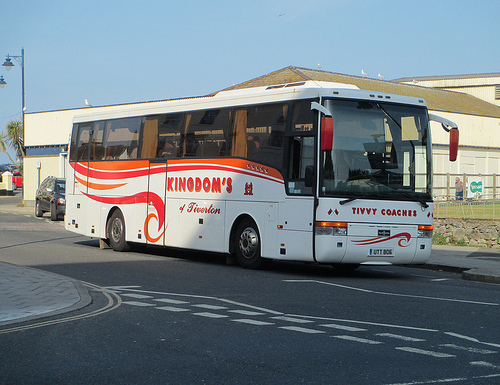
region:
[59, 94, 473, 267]
white, red and orange bus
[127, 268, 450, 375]
gray street with white lines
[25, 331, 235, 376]
gray street without lines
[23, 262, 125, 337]
gray sidewalk with lines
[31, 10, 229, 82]
white clouds against blue sky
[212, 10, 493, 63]
white clouds against blue sky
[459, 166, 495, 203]
green and white sign on fence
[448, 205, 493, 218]
brown and green grass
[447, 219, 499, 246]
gray brick wall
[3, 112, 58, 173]
brown and blue building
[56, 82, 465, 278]
Passenger bus is white and red.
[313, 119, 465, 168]
Mirrors in front of bus are orange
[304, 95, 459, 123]
Holders of mirrors are white.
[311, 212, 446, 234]
Orange light in front of bus.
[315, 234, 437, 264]
Bumper of bus has a plate.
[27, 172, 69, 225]
Black car behind bus.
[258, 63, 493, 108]
Roof of house is brown.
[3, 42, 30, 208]
Light pole near building.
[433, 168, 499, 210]
Wood fence in front of building.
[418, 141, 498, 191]
Building has white doors.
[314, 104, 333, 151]
the side mirror of a bus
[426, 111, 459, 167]
the side mirror of a bus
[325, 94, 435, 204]
the windshield of a bus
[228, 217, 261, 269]
the tire of a bus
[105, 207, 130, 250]
the tire of a bus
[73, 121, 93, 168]
the window of a bus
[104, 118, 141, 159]
the window of a bus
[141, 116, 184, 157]
the window of a bus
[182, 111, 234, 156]
the window of a bus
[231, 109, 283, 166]
the window of a bus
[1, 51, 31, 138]
Lamp posts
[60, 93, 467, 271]
Red and white coach bus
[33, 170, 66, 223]
Black SUV behind a buss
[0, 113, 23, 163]
Palm trees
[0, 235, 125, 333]
Corner of a sidewalk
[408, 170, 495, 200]
Fence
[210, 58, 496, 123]
Brown roof of a building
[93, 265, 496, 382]
Markings on street pavement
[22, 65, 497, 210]
White building behind a coach bus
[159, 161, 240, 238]
Name of the coach bus written on it's side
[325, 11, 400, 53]
part of the sky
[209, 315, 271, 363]
part of the road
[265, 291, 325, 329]
part of some white lines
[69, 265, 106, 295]
edge of the road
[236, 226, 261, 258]
part of a rim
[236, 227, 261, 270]
part of a wheel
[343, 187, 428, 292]
front of a bus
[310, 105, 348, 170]
part of a side mirror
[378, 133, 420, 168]
part of a window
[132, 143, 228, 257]
side of a bus